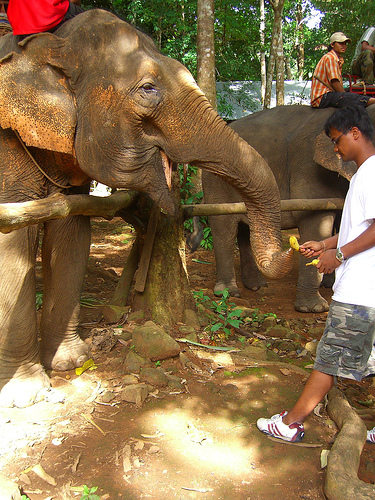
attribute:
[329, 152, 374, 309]
shirt — white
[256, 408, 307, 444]
shoe — white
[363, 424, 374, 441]
shoe — white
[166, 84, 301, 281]
trunk — curved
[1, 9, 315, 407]
elephant — brown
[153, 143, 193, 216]
mouth — open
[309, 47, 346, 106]
shirt — plaid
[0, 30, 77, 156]
ear — orange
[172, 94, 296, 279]
trunk — long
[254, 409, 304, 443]
shoe — red, white